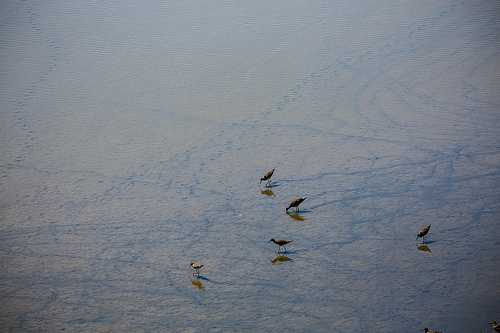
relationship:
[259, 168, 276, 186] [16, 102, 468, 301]
bird walking in water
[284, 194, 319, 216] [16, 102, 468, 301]
bird walking in water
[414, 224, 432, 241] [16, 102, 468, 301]
bird walking in water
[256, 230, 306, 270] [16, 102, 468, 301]
bird walking in water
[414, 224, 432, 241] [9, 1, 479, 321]
bird walking in water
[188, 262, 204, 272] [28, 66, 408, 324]
bird in water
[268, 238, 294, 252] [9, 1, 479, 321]
bird in water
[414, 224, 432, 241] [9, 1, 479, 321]
bird in water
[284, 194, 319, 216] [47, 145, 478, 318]
bird in water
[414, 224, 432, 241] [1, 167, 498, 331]
bird in water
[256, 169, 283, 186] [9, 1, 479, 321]
bird in water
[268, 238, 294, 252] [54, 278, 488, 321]
bird in sand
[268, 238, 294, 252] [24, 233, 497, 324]
bird in sand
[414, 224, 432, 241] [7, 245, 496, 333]
bird in sand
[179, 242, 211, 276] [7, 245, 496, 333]
bird on sand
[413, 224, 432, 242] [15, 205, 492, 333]
bird on sand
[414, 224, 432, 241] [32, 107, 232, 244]
bird in water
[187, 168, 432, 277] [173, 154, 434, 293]
birds flock of birds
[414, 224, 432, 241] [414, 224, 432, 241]
bird with bird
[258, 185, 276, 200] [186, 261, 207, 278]
shadow of bird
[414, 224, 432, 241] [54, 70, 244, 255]
bird on ice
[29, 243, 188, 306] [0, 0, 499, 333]
lines on iced surface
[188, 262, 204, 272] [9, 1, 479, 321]
bird on water